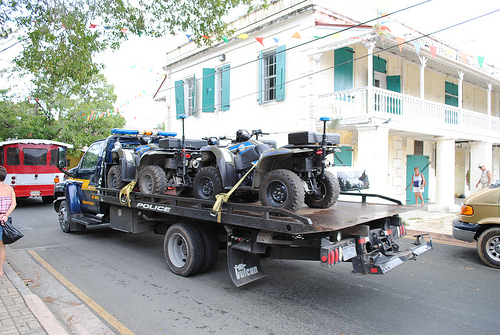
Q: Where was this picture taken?
A: The street.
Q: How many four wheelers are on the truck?
A: Two.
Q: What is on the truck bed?
A: Four wheelers.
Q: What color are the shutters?
A: Blue.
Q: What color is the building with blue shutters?
A: White.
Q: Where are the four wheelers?
A: On flatbed truck.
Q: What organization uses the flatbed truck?
A: Police.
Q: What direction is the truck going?
A: Left.